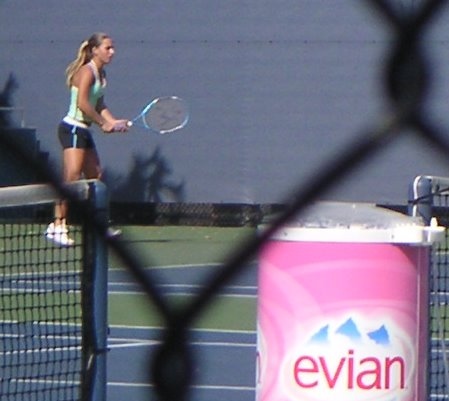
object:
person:
[46, 33, 130, 247]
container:
[257, 200, 448, 401]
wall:
[1, 3, 448, 207]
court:
[1, 252, 448, 304]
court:
[0, 319, 448, 400]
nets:
[2, 178, 448, 400]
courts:
[1, 250, 449, 400]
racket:
[127, 94, 191, 136]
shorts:
[57, 121, 96, 151]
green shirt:
[62, 61, 109, 130]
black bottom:
[0, 203, 448, 230]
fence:
[1, 2, 448, 400]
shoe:
[44, 223, 75, 247]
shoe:
[106, 224, 122, 236]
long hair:
[65, 34, 113, 89]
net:
[1, 176, 107, 400]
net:
[413, 176, 449, 400]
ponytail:
[63, 40, 90, 88]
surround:
[2, 221, 448, 335]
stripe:
[72, 124, 77, 148]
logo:
[295, 320, 407, 391]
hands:
[102, 119, 131, 133]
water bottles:
[261, 217, 420, 228]